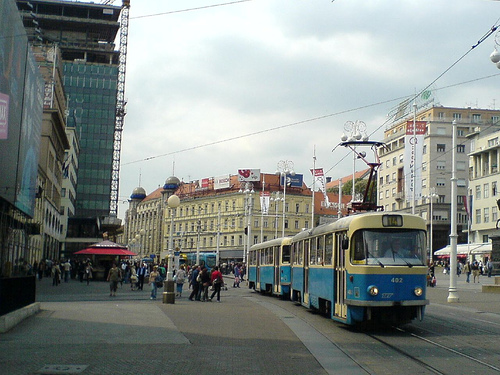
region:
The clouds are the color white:
[146, 30, 400, 86]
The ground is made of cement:
[87, 303, 242, 359]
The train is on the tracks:
[241, 208, 443, 335]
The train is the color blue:
[278, 263, 343, 295]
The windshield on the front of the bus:
[350, 228, 430, 267]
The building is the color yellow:
[129, 178, 276, 246]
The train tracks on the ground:
[351, 330, 498, 371]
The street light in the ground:
[156, 185, 176, 300]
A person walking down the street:
[100, 257, 127, 297]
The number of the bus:
[377, 210, 402, 227]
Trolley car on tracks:
[240, 207, 487, 362]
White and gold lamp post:
[157, 193, 190, 308]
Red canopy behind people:
[71, 236, 136, 281]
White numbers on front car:
[384, 272, 410, 289]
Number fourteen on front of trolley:
[375, 211, 407, 231]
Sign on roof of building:
[233, 160, 262, 187]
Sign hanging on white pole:
[255, 187, 272, 217]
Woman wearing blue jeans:
[144, 262, 164, 304]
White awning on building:
[437, 236, 479, 261]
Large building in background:
[124, 164, 316, 275]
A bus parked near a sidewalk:
[284, 211, 443, 320]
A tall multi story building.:
[333, 93, 495, 248]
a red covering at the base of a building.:
[72, 236, 140, 265]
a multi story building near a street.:
[121, 182, 181, 274]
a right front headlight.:
[364, 277, 392, 304]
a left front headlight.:
[404, 272, 432, 299]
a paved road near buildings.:
[230, 263, 497, 373]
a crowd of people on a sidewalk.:
[97, 243, 247, 317]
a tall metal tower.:
[99, 0, 137, 243]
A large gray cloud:
[133, 0, 498, 117]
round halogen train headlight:
[365, 282, 381, 299]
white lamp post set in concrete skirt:
[161, 194, 181, 302]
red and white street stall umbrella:
[77, 239, 134, 254]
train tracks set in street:
[363, 333, 498, 372]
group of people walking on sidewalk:
[108, 256, 228, 304]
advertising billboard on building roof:
[239, 168, 259, 180]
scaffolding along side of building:
[108, 3, 130, 214]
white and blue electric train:
[247, 214, 427, 329]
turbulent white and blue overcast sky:
[135, 21, 405, 93]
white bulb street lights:
[339, 127, 385, 148]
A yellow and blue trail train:
[340, 208, 439, 332]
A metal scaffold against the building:
[109, 0, 131, 220]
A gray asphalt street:
[137, 308, 257, 367]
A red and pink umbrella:
[74, 233, 139, 264]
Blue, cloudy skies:
[232, 60, 341, 127]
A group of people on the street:
[176, 260, 230, 304]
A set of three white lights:
[335, 116, 384, 159]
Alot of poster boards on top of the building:
[171, 165, 243, 195]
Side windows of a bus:
[292, 223, 336, 275]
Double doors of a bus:
[332, 221, 352, 328]